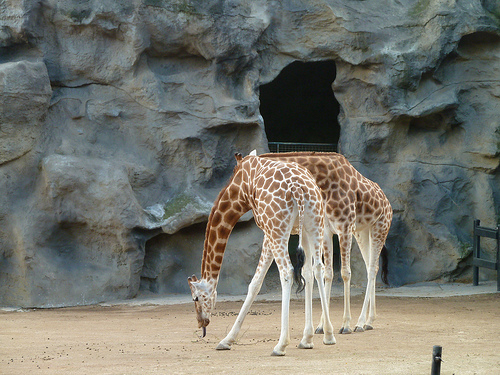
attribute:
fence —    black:
[468, 217, 498, 278]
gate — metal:
[463, 137, 498, 292]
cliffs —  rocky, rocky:
[5, 0, 497, 291]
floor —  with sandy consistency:
[3, 293, 498, 373]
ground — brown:
[96, 310, 181, 357]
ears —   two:
[181, 274, 205, 290]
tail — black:
[289, 231, 312, 290]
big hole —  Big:
[250, 54, 343, 154]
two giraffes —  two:
[176, 124, 410, 366]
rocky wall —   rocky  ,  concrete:
[0, 0, 498, 312]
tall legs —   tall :
[262, 197, 294, 358]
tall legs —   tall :
[216, 222, 273, 357]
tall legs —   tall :
[302, 194, 337, 345]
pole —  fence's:
[431, 346, 443, 370]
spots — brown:
[188, 151, 325, 279]